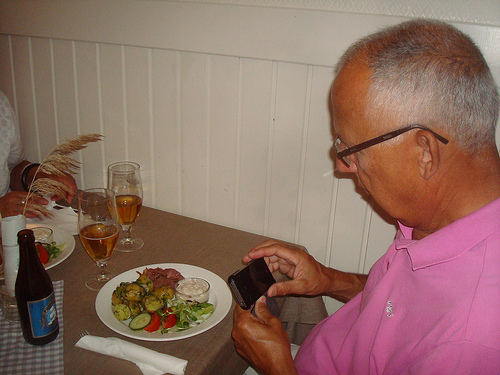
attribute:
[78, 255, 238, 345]
plate — white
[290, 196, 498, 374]
shirt — pink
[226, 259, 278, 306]
device — black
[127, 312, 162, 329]
cucumber — sliced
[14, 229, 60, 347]
bottle — dark brown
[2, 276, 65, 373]
mat — checkered, light grey, white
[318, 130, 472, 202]
glasses — black , Pair 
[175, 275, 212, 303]
dressing — salad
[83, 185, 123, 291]
glass — Slender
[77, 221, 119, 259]
beer — golden-colored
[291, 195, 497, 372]
polo shirt — pink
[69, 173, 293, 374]
table — square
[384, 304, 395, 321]
logo — white, embroidered, animal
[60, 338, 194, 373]
rolled napkin — white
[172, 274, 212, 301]
cup — small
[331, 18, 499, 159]
hair — gray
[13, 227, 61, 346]
beer — in bottle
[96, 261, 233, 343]
plate — white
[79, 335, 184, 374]
napkin — white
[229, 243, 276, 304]
digital camera — small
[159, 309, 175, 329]
tomato — sliced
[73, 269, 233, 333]
white plate — round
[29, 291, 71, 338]
label —   blue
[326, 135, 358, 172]
lenses — rectangular